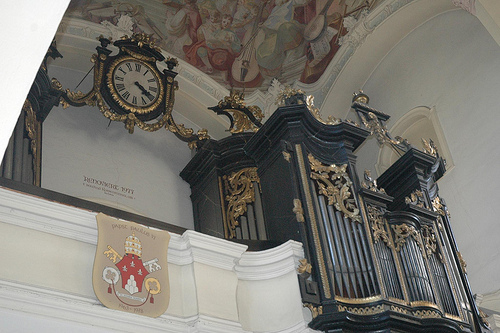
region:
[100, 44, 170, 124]
clock face hanging on wall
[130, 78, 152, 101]
black metal clock hands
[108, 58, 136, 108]
black roman numerals on clock face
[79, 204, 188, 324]
plaque hanging on wall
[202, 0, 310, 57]
design on building ceiling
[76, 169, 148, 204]
gold writing on building wall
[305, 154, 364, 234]
gold design on black column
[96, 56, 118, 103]
golden trim on clock face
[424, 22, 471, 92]
white paint on building wall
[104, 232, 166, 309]
design on tan plaque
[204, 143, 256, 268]
Section of a wallpaunit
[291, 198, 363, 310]
Section of a wallpaunit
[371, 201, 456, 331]
Section of a wallpaunit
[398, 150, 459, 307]
Section of a wallpaunit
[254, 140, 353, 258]
Section of a wallpaunit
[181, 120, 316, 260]
Section of a wallpaunit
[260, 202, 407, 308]
Section of a wallpaunit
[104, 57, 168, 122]
this is a clock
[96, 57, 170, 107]
the clock is black in color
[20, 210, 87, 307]
this is the wall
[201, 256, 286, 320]
the wall is white in color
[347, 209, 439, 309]
this is a cabinet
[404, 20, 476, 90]
this is a wall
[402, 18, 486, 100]
the wall is clear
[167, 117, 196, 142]
this is a metal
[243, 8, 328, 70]
this is the roof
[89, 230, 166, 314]
this is a badge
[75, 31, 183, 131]
a clock inside of a building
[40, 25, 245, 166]
a clock inside of a building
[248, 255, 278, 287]
part pf a line